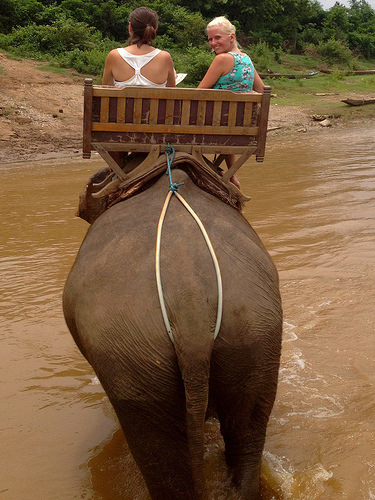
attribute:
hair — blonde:
[205, 13, 244, 55]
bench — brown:
[72, 77, 322, 181]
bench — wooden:
[78, 74, 271, 206]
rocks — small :
[310, 110, 340, 130]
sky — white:
[314, 0, 374, 15]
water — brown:
[296, 147, 364, 218]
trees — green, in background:
[2, 0, 372, 76]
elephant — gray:
[51, 162, 299, 496]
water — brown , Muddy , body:
[0, 123, 373, 495]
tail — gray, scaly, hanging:
[174, 342, 212, 499]